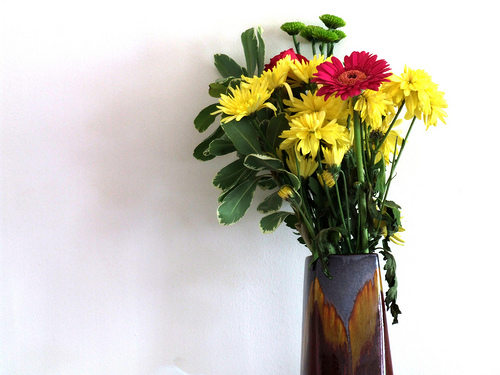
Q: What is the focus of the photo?
A: A vase with flowers.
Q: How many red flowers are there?
A: Two.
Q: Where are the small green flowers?
A: In the back center of the vase.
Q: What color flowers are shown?
A: Red, yellow, and green.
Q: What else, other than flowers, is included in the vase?
A: Green leaves.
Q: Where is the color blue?
A: On the vase.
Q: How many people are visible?
A: None.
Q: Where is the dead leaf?
A: Hanging from the right side of the bouquet.